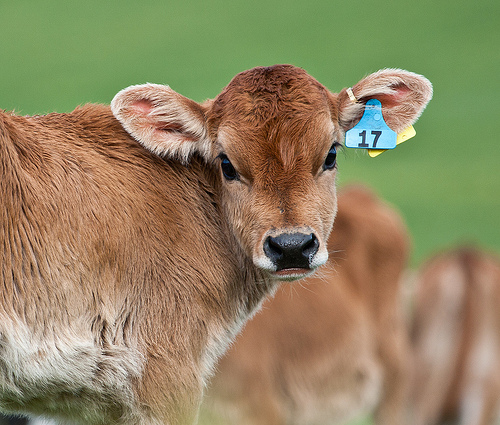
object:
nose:
[250, 222, 331, 271]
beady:
[215, 154, 259, 192]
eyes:
[213, 152, 238, 181]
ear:
[338, 62, 436, 151]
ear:
[105, 80, 217, 158]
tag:
[342, 105, 416, 158]